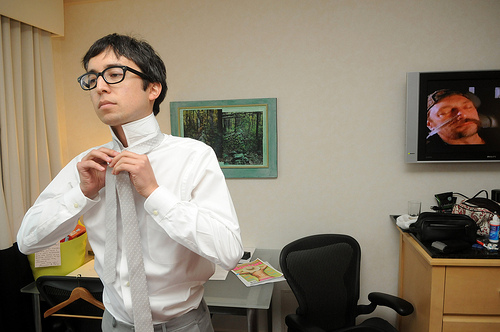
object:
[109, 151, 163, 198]
hand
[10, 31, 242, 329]
boy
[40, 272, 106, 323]
coat hanger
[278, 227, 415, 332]
chair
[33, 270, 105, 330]
chair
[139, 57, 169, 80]
hair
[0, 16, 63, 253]
curtains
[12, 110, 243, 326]
shirt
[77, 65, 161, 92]
glasses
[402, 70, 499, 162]
television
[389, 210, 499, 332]
cabinet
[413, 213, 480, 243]
kit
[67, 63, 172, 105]
glasses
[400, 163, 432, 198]
ground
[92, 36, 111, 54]
black hair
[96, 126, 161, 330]
grey tie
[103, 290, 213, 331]
bottoms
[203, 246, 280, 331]
table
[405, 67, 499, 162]
screen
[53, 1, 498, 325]
wall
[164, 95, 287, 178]
picture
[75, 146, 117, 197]
hand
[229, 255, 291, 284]
magazine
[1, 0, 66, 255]
window